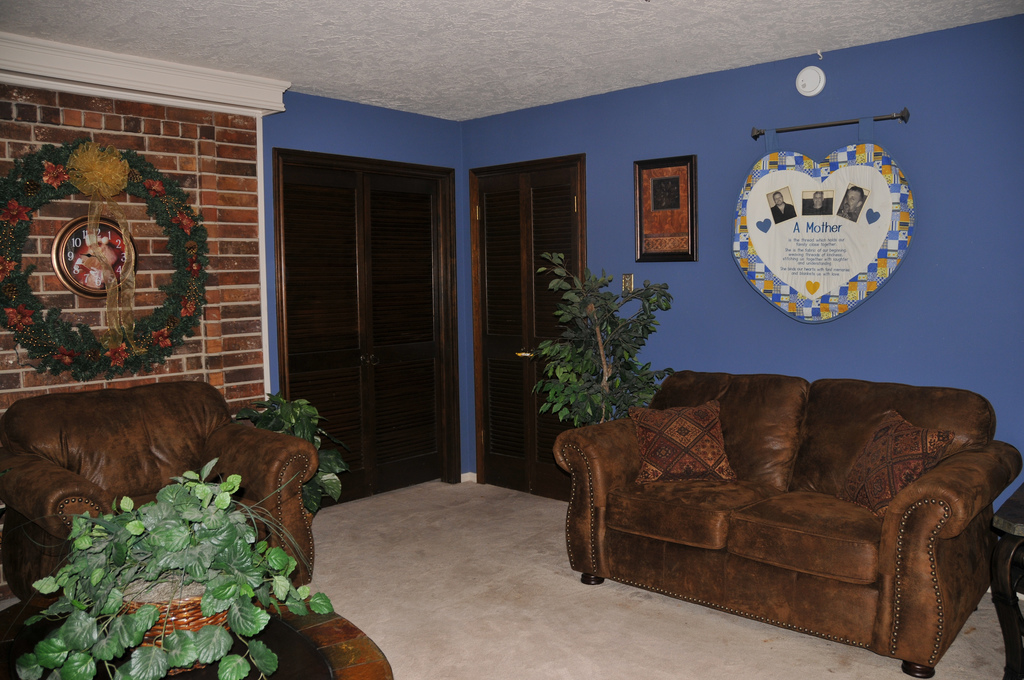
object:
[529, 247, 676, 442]
plant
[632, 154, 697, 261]
picture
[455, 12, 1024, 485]
wall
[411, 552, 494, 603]
rug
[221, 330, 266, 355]
bricks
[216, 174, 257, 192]
brick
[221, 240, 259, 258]
brick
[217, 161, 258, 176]
brick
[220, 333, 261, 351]
brick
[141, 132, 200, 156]
brick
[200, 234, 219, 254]
brick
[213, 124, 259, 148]
brick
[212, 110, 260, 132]
brick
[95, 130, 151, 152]
brick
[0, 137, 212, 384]
wreath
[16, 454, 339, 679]
plant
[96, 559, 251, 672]
basket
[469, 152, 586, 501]
door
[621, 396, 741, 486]
pillow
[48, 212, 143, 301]
clock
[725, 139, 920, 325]
heart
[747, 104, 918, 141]
bar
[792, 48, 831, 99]
alarm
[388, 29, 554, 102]
ceiling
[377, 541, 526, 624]
carpet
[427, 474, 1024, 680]
ground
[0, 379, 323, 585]
chair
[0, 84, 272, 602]
brick wall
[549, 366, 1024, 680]
couch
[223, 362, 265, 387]
brick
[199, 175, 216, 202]
brick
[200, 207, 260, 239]
brick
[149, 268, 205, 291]
brick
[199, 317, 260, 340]
brick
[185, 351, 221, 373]
brick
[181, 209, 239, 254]
brick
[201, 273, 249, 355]
brick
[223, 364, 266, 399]
brick